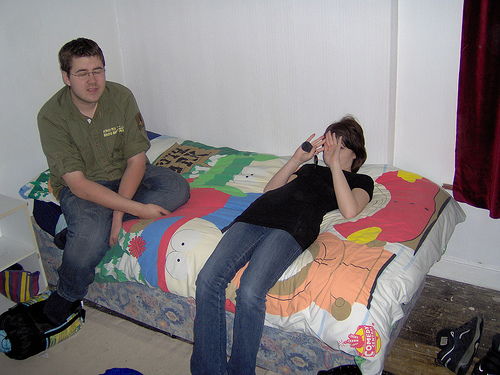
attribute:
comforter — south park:
[19, 129, 466, 359]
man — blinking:
[38, 36, 191, 323]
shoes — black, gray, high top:
[433, 312, 497, 374]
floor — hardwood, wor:
[1, 272, 497, 373]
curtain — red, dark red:
[452, 0, 499, 219]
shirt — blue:
[98, 366, 148, 374]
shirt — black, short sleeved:
[235, 162, 374, 250]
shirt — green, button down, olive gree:
[37, 80, 151, 196]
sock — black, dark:
[53, 223, 70, 251]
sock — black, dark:
[42, 291, 71, 323]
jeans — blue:
[189, 220, 304, 374]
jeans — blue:
[56, 163, 192, 302]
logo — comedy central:
[339, 321, 383, 359]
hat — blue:
[127, 215, 196, 294]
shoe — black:
[434, 314, 484, 372]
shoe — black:
[472, 333, 499, 373]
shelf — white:
[0, 228, 35, 282]